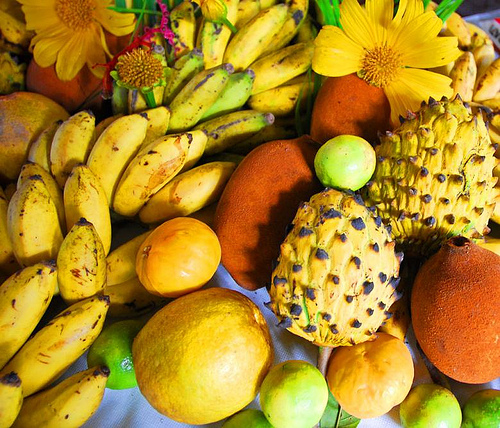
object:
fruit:
[323, 330, 415, 421]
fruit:
[265, 187, 404, 350]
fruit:
[361, 93, 499, 255]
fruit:
[49, 109, 98, 191]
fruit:
[169, 62, 233, 129]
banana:
[0, 294, 112, 399]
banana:
[0, 256, 59, 370]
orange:
[127, 282, 277, 427]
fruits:
[446, 51, 478, 102]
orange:
[1, 90, 71, 181]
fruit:
[398, 382, 462, 425]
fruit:
[460, 386, 500, 426]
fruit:
[313, 134, 378, 193]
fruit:
[133, 217, 221, 298]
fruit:
[86, 315, 156, 392]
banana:
[56, 217, 108, 305]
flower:
[309, 0, 459, 130]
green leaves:
[310, 0, 343, 30]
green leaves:
[433, 0, 465, 28]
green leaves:
[315, 390, 361, 426]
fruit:
[255, 358, 333, 426]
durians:
[215, 134, 327, 292]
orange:
[322, 330, 416, 420]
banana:
[60, 165, 115, 259]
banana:
[137, 161, 235, 228]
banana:
[13, 162, 66, 240]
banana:
[6, 174, 64, 269]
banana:
[13, 363, 110, 426]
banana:
[0, 369, 27, 424]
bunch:
[26, 107, 239, 228]